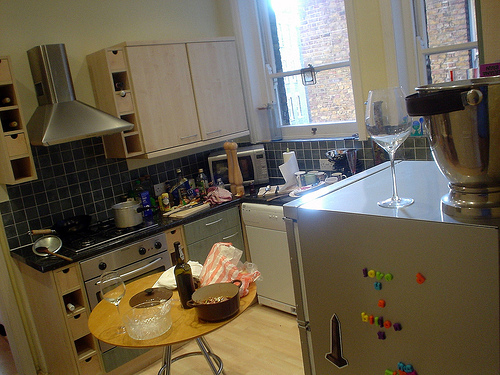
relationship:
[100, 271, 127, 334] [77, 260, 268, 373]
glass on table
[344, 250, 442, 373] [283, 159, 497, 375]
magnets on fridge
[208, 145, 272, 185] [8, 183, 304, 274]
microwave on counter top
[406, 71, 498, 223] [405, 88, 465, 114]
ice bucket with a handle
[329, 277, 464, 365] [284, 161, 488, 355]
magnets on side of refrigerator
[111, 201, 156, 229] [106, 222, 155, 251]
cooker on stove burner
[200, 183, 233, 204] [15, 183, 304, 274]
rag on counter top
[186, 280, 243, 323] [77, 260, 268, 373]
lid on table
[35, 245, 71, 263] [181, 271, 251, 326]
spoon rests in overturned lid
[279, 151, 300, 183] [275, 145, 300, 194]
holder in standing holder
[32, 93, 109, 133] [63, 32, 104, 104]
chimney on wall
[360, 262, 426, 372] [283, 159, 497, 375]
stickies on side of fridge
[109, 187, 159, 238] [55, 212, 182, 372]
cooker on stove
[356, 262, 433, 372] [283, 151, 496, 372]
letters on fridge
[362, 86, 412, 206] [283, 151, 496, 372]
glass on fridge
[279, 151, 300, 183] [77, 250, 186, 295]
holder near oven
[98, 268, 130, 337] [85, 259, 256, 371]
glass on edge of table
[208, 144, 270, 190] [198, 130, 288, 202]
microwave in corner